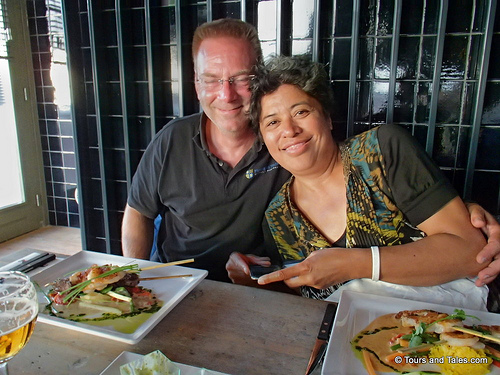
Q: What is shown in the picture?
A: A restaurant table.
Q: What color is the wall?
A: Black.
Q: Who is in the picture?
A: A couple.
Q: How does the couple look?
A: Happy.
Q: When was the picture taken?
A: At daytime.